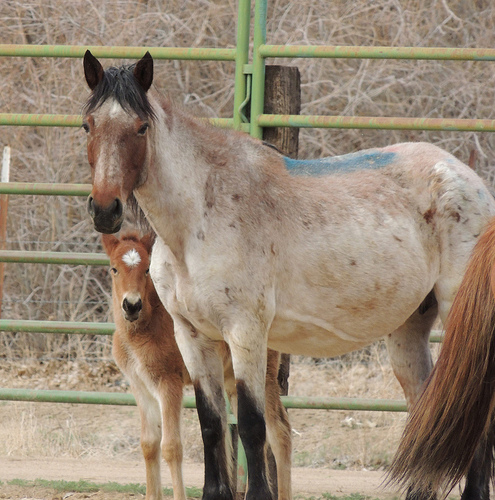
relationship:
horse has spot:
[95, 219, 314, 499] [115, 246, 148, 270]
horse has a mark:
[68, 40, 494, 500] [271, 141, 407, 184]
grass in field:
[6, 474, 392, 499] [4, 3, 429, 459]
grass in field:
[2, 5, 493, 383] [4, 3, 429, 459]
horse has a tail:
[68, 40, 494, 500] [386, 207, 492, 498]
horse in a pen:
[79, 46, 494, 500] [0, 12, 490, 454]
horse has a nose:
[95, 219, 314, 499] [119, 295, 148, 318]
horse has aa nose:
[68, 40, 494, 500] [83, 197, 128, 229]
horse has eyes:
[95, 219, 314, 499] [107, 260, 154, 277]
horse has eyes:
[68, 40, 494, 500] [77, 113, 152, 139]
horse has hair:
[68, 40, 494, 500] [80, 62, 151, 126]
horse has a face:
[95, 219, 314, 499] [104, 243, 158, 327]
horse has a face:
[68, 40, 494, 500] [76, 85, 160, 243]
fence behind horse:
[2, 15, 488, 423] [95, 219, 314, 499]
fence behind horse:
[2, 15, 488, 423] [68, 40, 494, 500]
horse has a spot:
[95, 219, 314, 499] [115, 246, 148, 270]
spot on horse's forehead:
[115, 246, 148, 270] [111, 237, 149, 272]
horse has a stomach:
[68, 40, 494, 500] [258, 281, 449, 356]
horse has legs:
[95, 219, 314, 499] [117, 378, 194, 499]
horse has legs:
[68, 40, 494, 500] [169, 305, 284, 499]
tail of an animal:
[386, 207, 492, 498] [384, 210, 494, 497]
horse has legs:
[68, 40, 494, 500] [379, 244, 467, 499]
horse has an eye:
[95, 219, 314, 499] [106, 264, 122, 277]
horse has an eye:
[95, 219, 314, 499] [141, 268, 151, 276]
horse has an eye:
[68, 40, 494, 500] [77, 121, 95, 136]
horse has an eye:
[68, 40, 494, 500] [131, 120, 154, 140]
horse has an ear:
[95, 219, 314, 499] [93, 227, 120, 253]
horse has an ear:
[68, 40, 494, 500] [75, 48, 106, 88]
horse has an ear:
[68, 40, 494, 500] [133, 50, 158, 91]